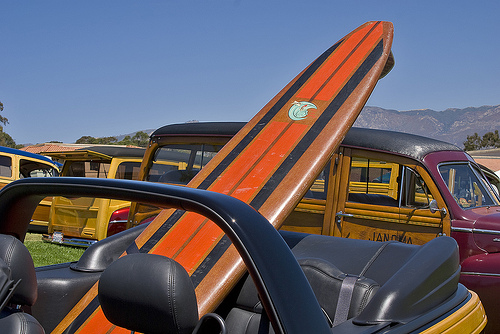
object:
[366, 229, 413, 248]
writing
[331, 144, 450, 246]
door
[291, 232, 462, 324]
seat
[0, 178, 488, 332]
car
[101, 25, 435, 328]
surfboard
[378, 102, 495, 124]
hill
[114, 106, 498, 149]
mountain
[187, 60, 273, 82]
clouds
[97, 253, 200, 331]
headrest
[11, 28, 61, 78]
clouds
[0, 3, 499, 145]
blue sky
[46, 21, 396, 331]
board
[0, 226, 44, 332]
seat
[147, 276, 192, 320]
seat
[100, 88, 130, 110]
sky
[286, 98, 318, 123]
logo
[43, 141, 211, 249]
car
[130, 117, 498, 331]
car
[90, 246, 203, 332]
seat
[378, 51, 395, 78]
fin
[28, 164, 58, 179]
glass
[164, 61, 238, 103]
clouds